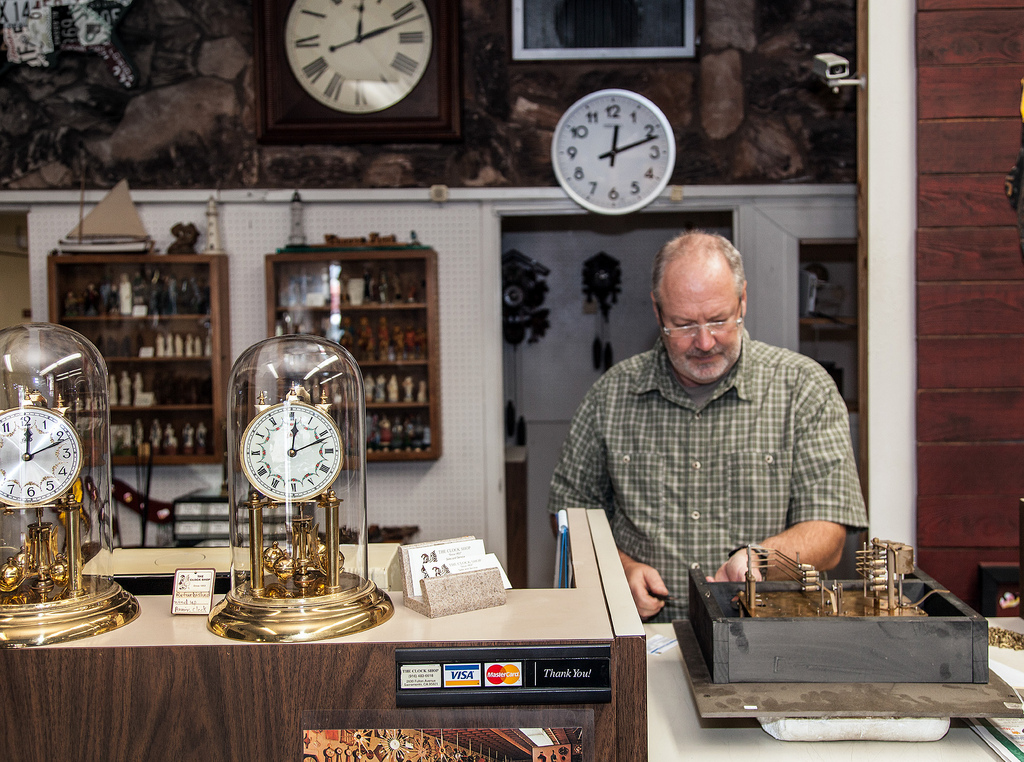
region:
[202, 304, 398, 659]
large clock sitting on the counter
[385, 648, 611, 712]
accepted payments sign on the counter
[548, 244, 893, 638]
man behind the counter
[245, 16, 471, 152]
large clock on the wall above the shelves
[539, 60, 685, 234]
small round white clock above the door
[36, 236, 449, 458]
two sets of shelves hanging on the wall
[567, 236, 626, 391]
cuckoo clock on the wall behind the man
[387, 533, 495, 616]
stand for cards on the counter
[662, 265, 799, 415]
man is wearing glasses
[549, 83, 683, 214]
A round clock is on a wall.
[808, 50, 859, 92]
A security camera is on a wall.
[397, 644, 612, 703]
The sign indicates acceptance of credit cards.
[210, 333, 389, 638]
A clock is under glass.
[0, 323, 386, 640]
Two clocks under glass have the same time.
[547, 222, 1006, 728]
A man is working on a clock.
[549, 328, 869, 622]
A man is wearing a green and white shirt.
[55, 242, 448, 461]
Two shelves are full of small objects.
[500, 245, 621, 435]
Two clocks have weights hanging under them.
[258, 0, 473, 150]
A round clock is in a square wooden frame.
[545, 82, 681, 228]
clock on the wall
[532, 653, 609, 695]
thank you sign on the front of the counter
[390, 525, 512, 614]
brochures on the counter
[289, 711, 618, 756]
picture on the front of the counter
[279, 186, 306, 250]
lighthouse on top of the shelf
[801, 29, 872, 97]
security camera on the wall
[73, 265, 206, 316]
statue figures on the shelf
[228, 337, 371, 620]
clock in a decorative case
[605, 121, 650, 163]
hands on the clock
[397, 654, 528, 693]
Sign showing which credit cards are accepted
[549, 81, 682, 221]
Round white wall clock with black numbers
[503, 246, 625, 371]
Two cuckoo clocks on the wall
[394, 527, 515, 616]
Business card holder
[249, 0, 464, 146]
Wall clock with Roman numerals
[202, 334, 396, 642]
Domed clock with Roman numerals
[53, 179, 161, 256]
Model sailboat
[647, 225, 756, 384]
Man wearing glasses and looking down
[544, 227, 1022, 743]
Man fixing a clock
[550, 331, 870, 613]
Checker pattern button down shirt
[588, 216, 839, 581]
a man standing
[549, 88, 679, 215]
a clock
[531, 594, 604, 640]
the counter top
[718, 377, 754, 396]
a collard shirt the man is wearing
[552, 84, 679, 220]
round clock with white face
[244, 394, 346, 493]
round clock with white face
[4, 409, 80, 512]
round clock with white face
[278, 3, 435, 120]
round clock with white face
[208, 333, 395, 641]
clear glass with gold framework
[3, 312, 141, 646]
clear glass with gold framework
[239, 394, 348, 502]
clock face with black numerals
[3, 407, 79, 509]
clock face with black numerals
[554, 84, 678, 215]
clock face with black numerals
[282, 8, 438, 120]
clock face with black numerals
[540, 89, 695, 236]
The clock above the man.